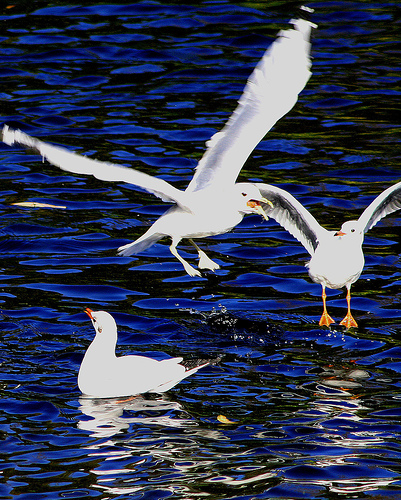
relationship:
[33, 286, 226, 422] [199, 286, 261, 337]
seagull over water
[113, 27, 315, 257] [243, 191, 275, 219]
bird with mouth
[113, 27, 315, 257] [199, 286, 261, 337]
bird on water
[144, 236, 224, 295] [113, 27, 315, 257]
leg under bird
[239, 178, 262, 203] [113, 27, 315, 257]
eye on bird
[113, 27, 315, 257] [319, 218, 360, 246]
bird has beak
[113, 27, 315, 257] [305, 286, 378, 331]
bird has feet